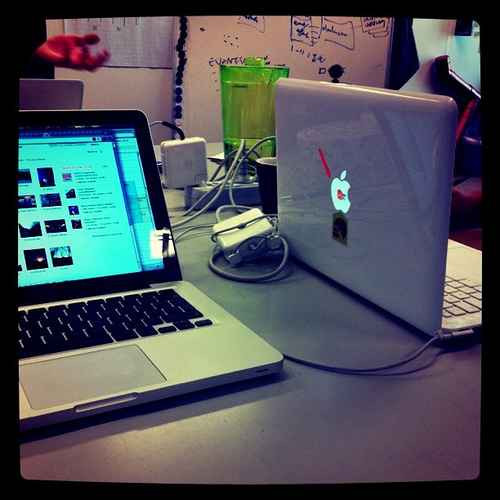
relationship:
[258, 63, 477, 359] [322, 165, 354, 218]
computer has logo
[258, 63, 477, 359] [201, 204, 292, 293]
computer has cord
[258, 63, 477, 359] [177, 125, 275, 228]
computer has wires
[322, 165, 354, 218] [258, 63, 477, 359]
logo on computer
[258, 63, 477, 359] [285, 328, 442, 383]
computer has wire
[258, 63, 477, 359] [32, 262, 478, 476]
computer on table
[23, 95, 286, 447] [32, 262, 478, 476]
computer on table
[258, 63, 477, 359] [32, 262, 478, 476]
computer on top of table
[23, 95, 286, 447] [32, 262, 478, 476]
computer on top of table